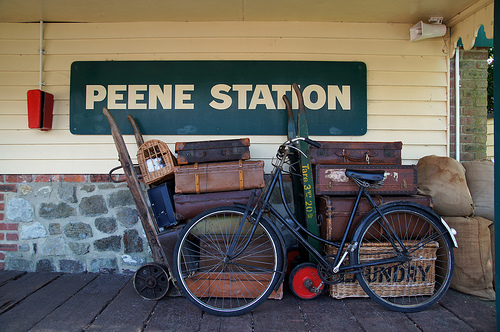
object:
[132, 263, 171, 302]
wheel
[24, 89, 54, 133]
object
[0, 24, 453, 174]
wall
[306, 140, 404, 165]
trunk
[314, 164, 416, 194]
trunk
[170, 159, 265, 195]
trunk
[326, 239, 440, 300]
trunk basket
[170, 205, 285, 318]
tire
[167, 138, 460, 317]
bicycle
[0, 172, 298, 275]
stone wall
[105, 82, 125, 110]
e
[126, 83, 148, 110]
e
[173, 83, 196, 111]
e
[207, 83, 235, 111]
letter s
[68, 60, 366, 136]
sign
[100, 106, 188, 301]
dolly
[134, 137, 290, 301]
pile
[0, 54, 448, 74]
siding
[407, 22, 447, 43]
loud speaker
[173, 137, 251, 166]
suitcase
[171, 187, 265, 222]
suitcase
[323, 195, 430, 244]
suitcase